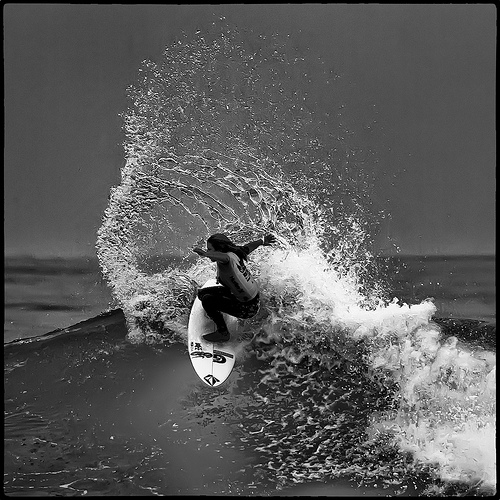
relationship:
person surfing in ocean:
[192, 232, 279, 342] [358, 233, 449, 396]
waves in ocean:
[47, 306, 200, 411] [314, 295, 486, 467]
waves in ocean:
[296, 285, 496, 496] [1, 255, 495, 496]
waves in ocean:
[4, 205, 495, 487] [1, 255, 495, 496]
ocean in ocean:
[358, 233, 449, 396] [1, 255, 495, 496]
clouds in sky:
[380, 64, 497, 185] [1, 2, 496, 259]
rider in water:
[194, 202, 260, 316] [176, 380, 319, 437]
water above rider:
[176, 380, 319, 437] [194, 202, 260, 316]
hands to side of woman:
[189, 239, 209, 256] [185, 231, 280, 346]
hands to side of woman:
[258, 226, 278, 245] [185, 231, 280, 346]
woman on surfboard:
[192, 231, 277, 343] [186, 277, 241, 389]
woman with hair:
[192, 231, 277, 343] [216, 238, 233, 250]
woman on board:
[192, 231, 277, 343] [187, 280, 239, 385]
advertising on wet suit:
[235, 257, 251, 283] [192, 232, 277, 343]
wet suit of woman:
[192, 232, 277, 343] [183, 224, 273, 344]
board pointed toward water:
[188, 350, 233, 390] [286, 286, 396, 418]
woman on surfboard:
[192, 231, 277, 343] [121, 254, 275, 389]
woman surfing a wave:
[192, 231, 277, 343] [266, 257, 409, 375]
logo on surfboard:
[203, 374, 220, 387] [187, 270, 239, 389]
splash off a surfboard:
[88, 63, 338, 338] [185, 279, 242, 401]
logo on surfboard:
[188, 338, 240, 390] [186, 270, 238, 410]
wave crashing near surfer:
[266, 257, 409, 375] [192, 229, 285, 339]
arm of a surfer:
[243, 232, 275, 253] [191, 229, 276, 341]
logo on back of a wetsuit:
[228, 256, 270, 295] [196, 247, 272, 321]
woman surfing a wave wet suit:
[192, 231, 277, 343] [197, 237, 265, 329]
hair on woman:
[216, 237, 229, 249] [192, 231, 277, 343]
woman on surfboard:
[192, 231, 277, 343] [183, 262, 243, 392]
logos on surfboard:
[190, 341, 233, 385] [187, 278, 237, 386]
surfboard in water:
[183, 262, 243, 392] [7, 253, 492, 498]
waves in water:
[296, 285, 496, 496] [7, 253, 492, 498]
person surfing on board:
[130, 199, 305, 394] [181, 274, 242, 388]